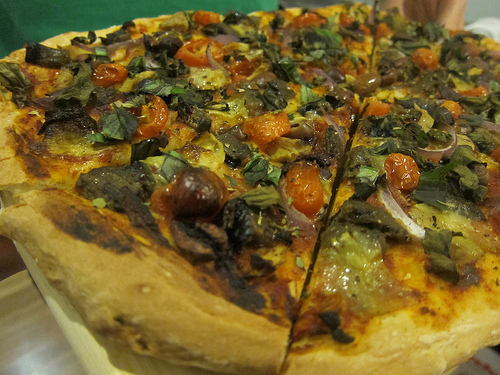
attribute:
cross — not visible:
[6, 6, 72, 28]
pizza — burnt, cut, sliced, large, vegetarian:
[12, 9, 499, 366]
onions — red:
[375, 186, 427, 238]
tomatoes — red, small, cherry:
[181, 36, 230, 67]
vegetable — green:
[283, 52, 306, 89]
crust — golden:
[12, 161, 333, 374]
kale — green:
[140, 78, 180, 93]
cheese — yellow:
[374, 227, 459, 305]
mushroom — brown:
[23, 43, 67, 65]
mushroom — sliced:
[103, 28, 131, 38]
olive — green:
[358, 70, 378, 92]